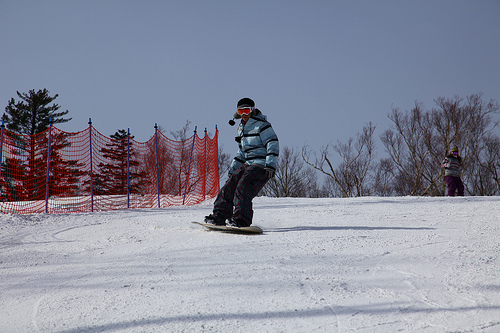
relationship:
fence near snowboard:
[95, 149, 128, 212] [191, 221, 264, 234]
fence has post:
[95, 149, 128, 212] [126, 129, 130, 212]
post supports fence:
[126, 129, 130, 212] [95, 149, 128, 212]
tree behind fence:
[11, 98, 51, 125] [95, 149, 128, 212]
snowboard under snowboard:
[190, 225, 259, 233] [191, 221, 264, 234]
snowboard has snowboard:
[191, 221, 264, 234] [190, 225, 259, 233]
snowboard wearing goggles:
[191, 221, 264, 234] [239, 107, 252, 115]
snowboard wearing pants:
[191, 221, 264, 234] [212, 172, 259, 221]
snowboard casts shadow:
[191, 221, 264, 234] [271, 223, 373, 239]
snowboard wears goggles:
[191, 221, 264, 234] [239, 107, 252, 115]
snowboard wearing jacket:
[191, 221, 264, 234] [237, 118, 271, 167]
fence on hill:
[95, 149, 128, 212] [9, 219, 139, 246]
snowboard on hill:
[191, 221, 264, 234] [9, 219, 139, 246]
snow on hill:
[357, 240, 367, 250] [9, 219, 139, 246]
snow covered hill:
[357, 240, 367, 250] [9, 219, 139, 246]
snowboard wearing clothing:
[191, 221, 264, 234] [245, 145, 265, 197]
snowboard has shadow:
[191, 221, 264, 234] [271, 223, 373, 239]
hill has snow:
[9, 219, 139, 246] [357, 240, 367, 250]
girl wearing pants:
[239, 114, 258, 127] [212, 172, 259, 221]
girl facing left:
[239, 114, 258, 127] [1, 26, 43, 58]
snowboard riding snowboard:
[191, 221, 264, 234] [190, 225, 259, 233]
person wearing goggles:
[444, 147, 465, 196] [455, 152, 459, 154]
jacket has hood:
[237, 118, 271, 167] [254, 115, 263, 120]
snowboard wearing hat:
[191, 221, 264, 234] [243, 100, 249, 103]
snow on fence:
[0, 194, 500, 333] [95, 149, 128, 212]